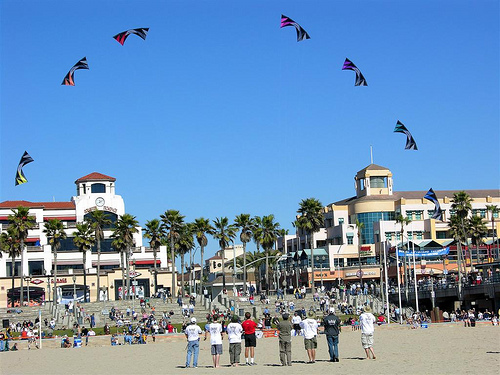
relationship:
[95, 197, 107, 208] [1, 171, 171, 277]
clock on building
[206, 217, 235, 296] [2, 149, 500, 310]
tree in city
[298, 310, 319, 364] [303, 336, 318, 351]
person wearing shorts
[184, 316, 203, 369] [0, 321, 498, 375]
man on beach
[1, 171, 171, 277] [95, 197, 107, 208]
building has clock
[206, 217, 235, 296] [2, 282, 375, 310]
tree by street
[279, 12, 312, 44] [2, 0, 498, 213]
kite in sky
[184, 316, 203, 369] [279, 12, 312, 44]
man watches kite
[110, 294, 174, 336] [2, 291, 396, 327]
people on stairs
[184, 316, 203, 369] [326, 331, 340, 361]
man in jeans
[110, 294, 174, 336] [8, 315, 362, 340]
people on grass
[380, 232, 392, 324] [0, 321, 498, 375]
light by beach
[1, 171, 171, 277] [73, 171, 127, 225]
building has a tower